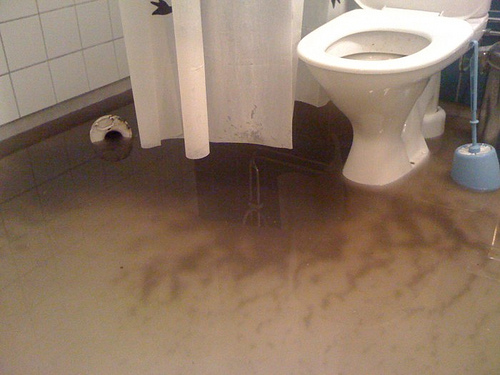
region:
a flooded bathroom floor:
[0, 99, 499, 374]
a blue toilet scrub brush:
[452, 40, 498, 187]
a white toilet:
[295, 0, 492, 192]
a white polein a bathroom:
[169, 3, 219, 161]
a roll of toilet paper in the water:
[90, 117, 136, 162]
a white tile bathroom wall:
[1, 1, 131, 126]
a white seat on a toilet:
[294, 11, 470, 72]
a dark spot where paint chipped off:
[150, 0, 171, 17]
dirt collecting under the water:
[378, 196, 471, 261]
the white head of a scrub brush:
[456, 143, 492, 160]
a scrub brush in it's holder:
[448, 38, 494, 188]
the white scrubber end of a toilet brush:
[457, 137, 487, 152]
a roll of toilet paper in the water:
[82, 110, 132, 155]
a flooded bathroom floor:
[1, 101, 496, 367]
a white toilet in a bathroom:
[291, 0, 491, 186]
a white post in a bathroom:
[166, 0, 211, 160]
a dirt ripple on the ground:
[320, 250, 391, 310]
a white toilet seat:
[296, 6, 482, 80]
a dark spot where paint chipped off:
[144, 0, 174, 16]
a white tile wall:
[0, 1, 131, 127]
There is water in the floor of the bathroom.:
[2, 100, 499, 374]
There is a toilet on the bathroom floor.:
[295, 1, 492, 188]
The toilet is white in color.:
[294, 1, 488, 192]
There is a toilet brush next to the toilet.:
[450, 39, 499, 192]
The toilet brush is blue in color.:
[447, 36, 499, 193]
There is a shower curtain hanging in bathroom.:
[115, 0, 350, 160]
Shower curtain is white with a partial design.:
[117, 1, 355, 158]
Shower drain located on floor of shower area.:
[88, 112, 135, 164]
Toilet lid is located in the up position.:
[351, 2, 493, 23]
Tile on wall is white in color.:
[2, 4, 131, 128]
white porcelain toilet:
[294, 0, 483, 197]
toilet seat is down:
[296, 7, 471, 84]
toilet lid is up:
[354, 0, 488, 21]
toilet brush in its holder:
[447, 37, 499, 194]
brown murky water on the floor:
[5, 65, 496, 374]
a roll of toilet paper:
[81, 105, 138, 157]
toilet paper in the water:
[81, 105, 142, 164]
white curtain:
[113, 0, 360, 165]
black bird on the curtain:
[150, 0, 178, 20]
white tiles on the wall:
[1, 1, 148, 144]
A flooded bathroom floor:
[70, 156, 448, 352]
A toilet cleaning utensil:
[450, 34, 497, 194]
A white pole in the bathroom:
[168, 6, 220, 166]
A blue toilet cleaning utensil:
[450, 33, 498, 191]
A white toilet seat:
[294, 3, 474, 82]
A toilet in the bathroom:
[296, 4, 455, 191]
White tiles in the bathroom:
[12, 16, 101, 76]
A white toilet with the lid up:
[292, 6, 459, 193]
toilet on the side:
[293, 5, 488, 198]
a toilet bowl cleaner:
[439, 26, 494, 204]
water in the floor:
[5, 114, 489, 349]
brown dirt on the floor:
[28, 120, 488, 322]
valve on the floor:
[85, 110, 142, 147]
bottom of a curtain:
[120, 3, 342, 170]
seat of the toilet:
[290, 9, 476, 81]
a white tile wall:
[8, 0, 134, 124]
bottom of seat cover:
[354, 0, 483, 22]